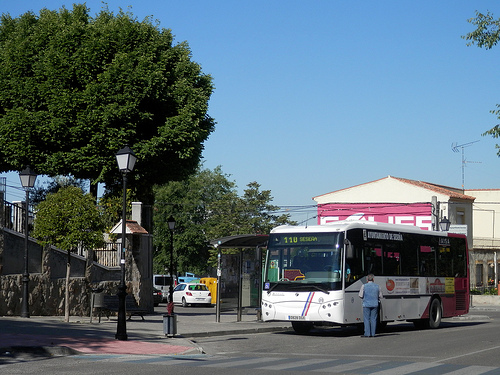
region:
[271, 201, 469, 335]
transit bus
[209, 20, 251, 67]
white clouds in blue sky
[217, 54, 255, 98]
white clouds in blue sky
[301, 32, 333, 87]
white clouds in blue sky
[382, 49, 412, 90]
white clouds in blue sky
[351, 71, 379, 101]
white clouds in blue sky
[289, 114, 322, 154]
white clouds in blue sky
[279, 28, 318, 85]
white clouds in blue sky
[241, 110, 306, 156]
white clouds in blue sky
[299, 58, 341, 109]
white clouds in blue sky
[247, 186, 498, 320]
CITY BUS ON PAVED ROAD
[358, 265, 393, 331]
PERSON IN BLUE BY BUS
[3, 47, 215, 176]
TALL TREE ON LEFT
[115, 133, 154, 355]
STREET LAMP OVER STREET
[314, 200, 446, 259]
LARGE PINK SIGN ON BUILDING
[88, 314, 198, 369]
RED SIDE WALK NEAR STREET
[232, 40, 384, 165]
BLUE SKY OVERHEAD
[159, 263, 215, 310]
WHITE HATCHBACK IN LOT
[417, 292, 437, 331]
BLACK RIBBER TIRE ON BUS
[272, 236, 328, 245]
GREEN DIGITAL READ OUT ON BUS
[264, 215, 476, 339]
white transit bus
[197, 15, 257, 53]
white clouds in blue sky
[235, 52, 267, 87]
white clouds in blue sky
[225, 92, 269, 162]
white clouds in blue sky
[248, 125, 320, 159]
white clouds in blue sky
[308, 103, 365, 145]
white clouds in blue sky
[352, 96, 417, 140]
white clouds in blue sky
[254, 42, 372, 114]
white clouds in blue sky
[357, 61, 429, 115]
white clouds in blue sky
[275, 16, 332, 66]
white clouds in blue sky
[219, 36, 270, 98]
white clouds in blue sky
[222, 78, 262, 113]
white clouds in blue sky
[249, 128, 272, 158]
white clouds in blue sky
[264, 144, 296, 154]
white clouds in blue sky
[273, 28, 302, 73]
white clouds in blue sky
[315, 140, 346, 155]
white clouds in blue sky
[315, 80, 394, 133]
white clouds in blue sky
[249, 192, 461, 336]
white passenger bus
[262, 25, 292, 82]
white clouds in blue sky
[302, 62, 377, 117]
white clouds in blue sky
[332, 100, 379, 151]
white clouds in blue sky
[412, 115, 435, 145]
white clouds in blue sky